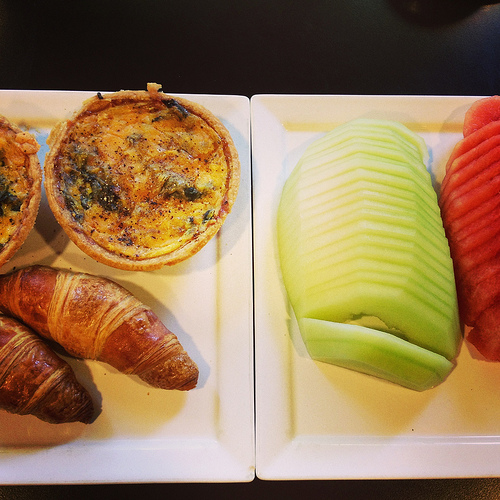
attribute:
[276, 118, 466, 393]
fruit — sliced, thinly sliced, green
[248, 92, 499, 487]
plate — white, square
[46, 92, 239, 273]
quiche — small, round, going to be eaten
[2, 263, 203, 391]
croissant — going to be eaten, brown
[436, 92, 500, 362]
melon — sliced, red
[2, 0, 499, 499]
table — visble, black, clean